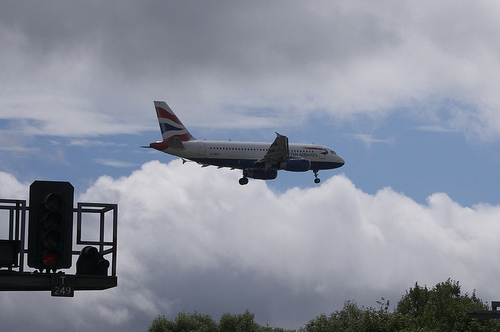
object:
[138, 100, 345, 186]
plane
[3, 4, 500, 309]
air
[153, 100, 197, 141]
tail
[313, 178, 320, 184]
wheels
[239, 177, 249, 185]
wheels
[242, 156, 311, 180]
engines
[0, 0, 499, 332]
clouds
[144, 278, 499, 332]
trees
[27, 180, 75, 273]
light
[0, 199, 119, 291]
catwalk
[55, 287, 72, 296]
numbers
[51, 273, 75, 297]
sign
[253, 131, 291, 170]
wing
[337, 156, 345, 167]
nose